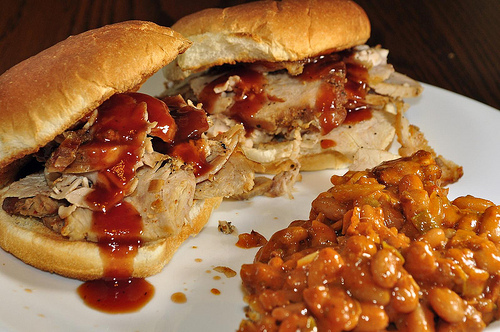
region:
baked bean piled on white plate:
[370, 245, 397, 285]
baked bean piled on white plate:
[340, 262, 386, 302]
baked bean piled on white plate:
[251, 261, 281, 287]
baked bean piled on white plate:
[353, 300, 385, 330]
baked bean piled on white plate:
[475, 245, 495, 280]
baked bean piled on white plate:
[301, 285, 363, 329]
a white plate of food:
[11, 8, 486, 319]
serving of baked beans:
[258, 155, 488, 325]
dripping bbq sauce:
[68, 233, 167, 311]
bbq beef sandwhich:
[8, 16, 260, 288]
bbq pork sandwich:
[169, 5, 437, 184]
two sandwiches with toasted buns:
[3, 10, 438, 275]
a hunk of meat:
[141, 143, 231, 234]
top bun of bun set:
[180, 0, 373, 82]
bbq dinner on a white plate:
[6, 3, 488, 321]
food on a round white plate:
[2, 8, 499, 325]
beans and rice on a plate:
[288, 176, 465, 320]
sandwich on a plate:
[24, 38, 224, 263]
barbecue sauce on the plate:
[82, 155, 136, 304]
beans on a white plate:
[278, 175, 448, 306]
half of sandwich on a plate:
[26, 25, 254, 257]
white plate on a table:
[403, 49, 493, 147]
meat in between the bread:
[200, 60, 397, 148]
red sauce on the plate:
[78, 268, 141, 314]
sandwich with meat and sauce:
[27, 56, 251, 243]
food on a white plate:
[51, 8, 438, 329]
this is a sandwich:
[12, 23, 197, 270]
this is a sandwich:
[170, 0, 391, 160]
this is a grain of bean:
[368, 245, 403, 289]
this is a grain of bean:
[405, 232, 438, 280]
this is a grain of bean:
[355, 296, 383, 328]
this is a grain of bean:
[311, 197, 358, 234]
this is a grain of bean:
[395, 169, 434, 197]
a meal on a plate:
[12, 19, 469, 327]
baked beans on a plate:
[245, 165, 468, 309]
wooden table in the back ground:
[8, 8, 74, 43]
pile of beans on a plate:
[252, 159, 488, 288]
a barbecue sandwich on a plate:
[204, 20, 394, 162]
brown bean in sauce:
[431, 287, 463, 317]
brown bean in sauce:
[413, 303, 431, 330]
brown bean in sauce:
[391, 278, 418, 306]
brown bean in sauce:
[371, 245, 398, 291]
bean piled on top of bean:
[370, 245, 398, 288]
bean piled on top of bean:
[337, 262, 390, 304]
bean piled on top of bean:
[388, 271, 419, 313]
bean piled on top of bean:
[397, 300, 436, 330]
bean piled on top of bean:
[424, 283, 463, 322]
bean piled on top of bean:
[403, 239, 442, 280]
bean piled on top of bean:
[417, 223, 451, 249]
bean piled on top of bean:
[452, 197, 495, 212]